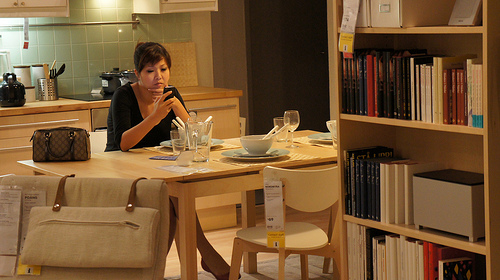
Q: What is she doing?
A: Communicating.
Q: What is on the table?
A: Glasses.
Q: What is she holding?
A: Phone.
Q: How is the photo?
A: Clear.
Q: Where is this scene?
A: In a house.